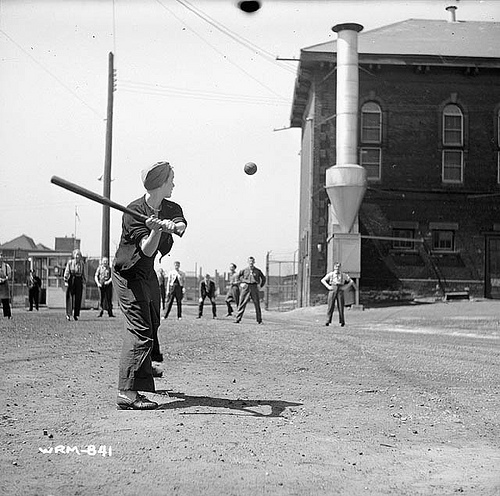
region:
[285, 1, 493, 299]
A BLACK HISTORY BUILDING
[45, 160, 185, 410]
BOY HOLDING BAT TO BAT THE BALL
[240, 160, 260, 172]
A ROUND BALL IN AIR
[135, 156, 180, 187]
HAS A CAP ON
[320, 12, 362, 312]
TALL WHITE PIPE BY THE BUILDING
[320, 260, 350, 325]
A MAN STANDING WATCHING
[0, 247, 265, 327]
A GROUP MEN WATCHING THE GAME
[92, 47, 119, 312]
A TALL LIGHT POLL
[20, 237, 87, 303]
A WHITE BOOTS IN THE BACK GROUND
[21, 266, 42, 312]
POLICE STANDING STANDING IN THE BACK WATCHING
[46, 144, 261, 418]
Baseball game school recess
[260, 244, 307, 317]
Yard gate wide open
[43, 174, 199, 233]
Bat held securely hands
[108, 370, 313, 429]
Shadow player bat ground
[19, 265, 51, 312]
Officer onlooking game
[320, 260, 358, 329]
White shirt suspenders hands hips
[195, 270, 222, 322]
Person stooped hands knees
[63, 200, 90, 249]
Flag flies flag pole distance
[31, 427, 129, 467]
Photograph marked WRM-841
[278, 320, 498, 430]
Slight impression tire tracks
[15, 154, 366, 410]
Kids playing ball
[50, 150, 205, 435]
Kid holding bat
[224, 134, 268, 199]
Ball in the air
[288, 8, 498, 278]
Old brick building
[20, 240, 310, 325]
Players are in the field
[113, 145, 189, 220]
Boy is wearing a hat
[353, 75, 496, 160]
Windows on the side of building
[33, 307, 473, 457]
Ground has dirt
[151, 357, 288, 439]
Shadow of player on ground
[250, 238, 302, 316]
Fence is by the building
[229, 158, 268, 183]
ball is small and round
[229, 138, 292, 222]
ball is small and round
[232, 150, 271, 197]
ball is small and round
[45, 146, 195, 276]
wooden base ball bat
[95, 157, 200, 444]
woman batting base ball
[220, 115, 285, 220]
baseball flying in air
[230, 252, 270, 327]
adult outfielder playing baseball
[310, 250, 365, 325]
adult outfielder playing baseball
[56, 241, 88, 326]
adult outfielder playing baseball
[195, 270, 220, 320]
outfielder playing baseball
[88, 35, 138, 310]
wooden power pole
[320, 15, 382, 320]
silo on side of building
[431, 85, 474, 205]
window in brick building